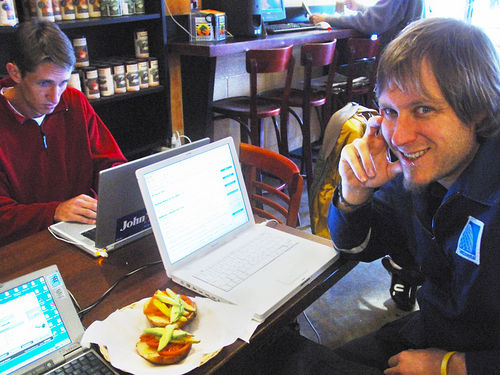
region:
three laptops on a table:
[0, 125, 354, 373]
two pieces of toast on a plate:
[101, 287, 229, 368]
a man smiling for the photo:
[331, 12, 498, 208]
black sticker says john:
[106, 211, 156, 238]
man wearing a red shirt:
[0, 15, 125, 220]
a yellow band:
[429, 344, 461, 374]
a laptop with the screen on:
[155, 130, 308, 304]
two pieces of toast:
[143, 288, 201, 366]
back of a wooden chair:
[237, 136, 310, 220]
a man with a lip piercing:
[378, 12, 488, 192]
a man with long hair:
[373, 31, 499, 183]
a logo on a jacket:
[453, 215, 487, 269]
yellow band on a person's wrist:
[427, 347, 464, 369]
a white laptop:
[140, 166, 320, 281]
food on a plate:
[93, 291, 205, 361]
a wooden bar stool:
[211, 34, 296, 131]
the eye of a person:
[411, 95, 439, 120]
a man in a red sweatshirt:
[2, 23, 107, 217]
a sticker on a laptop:
[106, 205, 146, 239]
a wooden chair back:
[247, 145, 306, 204]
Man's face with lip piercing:
[365, 17, 499, 189]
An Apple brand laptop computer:
[135, 135, 335, 315]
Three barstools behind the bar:
[175, 19, 397, 111]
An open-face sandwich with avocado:
[111, 291, 230, 366]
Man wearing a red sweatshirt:
[0, 17, 149, 253]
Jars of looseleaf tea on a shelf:
[24, 2, 175, 98]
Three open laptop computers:
[0, 130, 317, 372]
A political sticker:
[112, 204, 153, 251]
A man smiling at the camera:
[341, 15, 498, 220]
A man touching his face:
[309, 9, 499, 209]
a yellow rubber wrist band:
[433, 350, 458, 372]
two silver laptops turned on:
[57, 135, 349, 315]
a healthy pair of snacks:
[123, 277, 218, 371]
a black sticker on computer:
[108, 199, 183, 248]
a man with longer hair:
[356, 3, 491, 193]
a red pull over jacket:
[0, 92, 148, 258]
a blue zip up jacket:
[321, 125, 498, 370]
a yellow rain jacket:
[313, 95, 373, 245]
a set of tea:
[55, 35, 172, 110]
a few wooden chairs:
[216, 30, 410, 148]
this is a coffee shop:
[18, 9, 497, 354]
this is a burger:
[145, 314, 196, 365]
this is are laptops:
[58, 183, 260, 298]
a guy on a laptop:
[11, 76, 124, 213]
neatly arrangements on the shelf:
[44, 8, 183, 90]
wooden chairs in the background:
[193, 87, 328, 211]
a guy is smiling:
[371, 91, 496, 191]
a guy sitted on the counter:
[268, 11, 400, 30]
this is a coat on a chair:
[339, 103, 361, 140]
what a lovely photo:
[3, 75, 463, 373]